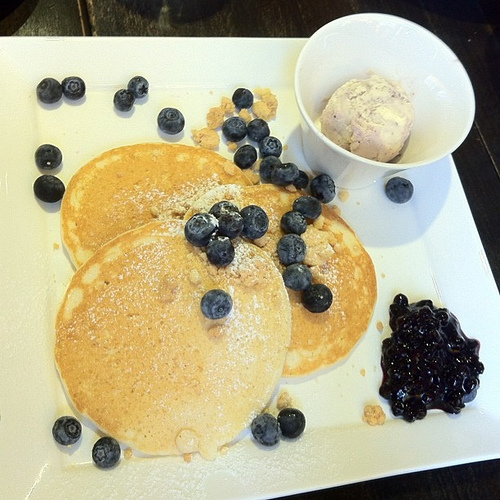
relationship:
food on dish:
[33, 77, 481, 470] [0, 35, 500, 500]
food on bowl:
[18, 137, 380, 341] [294, 11, 475, 193]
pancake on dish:
[57, 215, 294, 460] [0, 35, 500, 500]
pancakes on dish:
[58, 133, 374, 462] [292, 12, 476, 191]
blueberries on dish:
[221, 85, 271, 143] [292, 12, 476, 191]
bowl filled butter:
[294, 11, 475, 193] [315, 61, 420, 166]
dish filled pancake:
[0, 35, 500, 500] [56, 130, 273, 282]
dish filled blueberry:
[0, 35, 500, 500] [47, 408, 81, 448]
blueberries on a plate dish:
[379, 293, 482, 424] [0, 35, 500, 500]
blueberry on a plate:
[389, 175, 416, 204] [392, 212, 482, 294]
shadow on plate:
[287, 158, 467, 251] [286, 12, 478, 206]